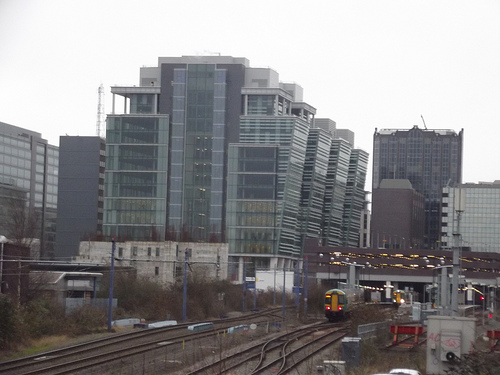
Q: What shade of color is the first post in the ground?
A: Blue.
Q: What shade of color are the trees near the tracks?
A: Brown.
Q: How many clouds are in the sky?
A: Zero.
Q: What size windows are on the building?
A: Large.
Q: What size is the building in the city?
A: Large.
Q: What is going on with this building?
A: The building is under construction.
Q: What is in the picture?
A: A high rise office building.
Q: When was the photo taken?
A: During the day.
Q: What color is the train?
A: Yellow.